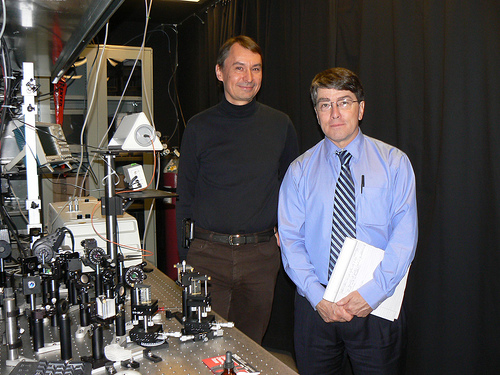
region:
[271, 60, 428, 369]
man standing wearing blue pants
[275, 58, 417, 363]
man standing holding white folder and blue long sleeve shirt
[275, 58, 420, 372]
man wearing blue striped tie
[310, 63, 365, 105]
dark hair on man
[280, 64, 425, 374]
man wearing glasses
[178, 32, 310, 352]
man standing wearing brown pants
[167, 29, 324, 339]
man wearing black shirt and black belt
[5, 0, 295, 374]
metal table with scientific equipment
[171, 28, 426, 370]
two scientists posing in picture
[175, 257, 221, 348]
microscope on metal table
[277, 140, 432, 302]
shirt on the person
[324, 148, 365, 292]
tie on the man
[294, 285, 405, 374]
pants on the person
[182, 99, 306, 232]
shirt on the person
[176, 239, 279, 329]
pants on the person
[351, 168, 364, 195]
pen in person's pocket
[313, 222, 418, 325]
paper in person's arm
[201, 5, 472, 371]
curtain behind the men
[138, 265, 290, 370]
table with equipment on it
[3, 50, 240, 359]
equipment for testing and experiments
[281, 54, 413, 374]
the man with his hands at his waist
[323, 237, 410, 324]
the white papers under his arm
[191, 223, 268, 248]
the black leather belt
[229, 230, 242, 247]
the buckle on the belt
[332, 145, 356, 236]
the stripped tie on the mans shirt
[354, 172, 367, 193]
the black cap of the pen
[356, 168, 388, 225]
the pen in the mans breast pocket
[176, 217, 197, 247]
the phone clipped on the belt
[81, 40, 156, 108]
the white cabinet agianst the wall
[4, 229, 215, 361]
the equipment on the workbench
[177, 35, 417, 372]
the two men standing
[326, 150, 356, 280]
the long striped tie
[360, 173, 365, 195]
the pen in the pocket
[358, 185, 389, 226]
the pocket on the man's shirt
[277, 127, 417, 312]
the long sleeved blue shirt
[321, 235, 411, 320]
the papers in the man's hands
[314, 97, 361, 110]
the glasses on the man's face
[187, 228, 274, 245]
the belt on the man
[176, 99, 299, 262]
the dark long sleeved shirt on the man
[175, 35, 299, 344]
the man wearing brown pants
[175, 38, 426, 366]
two guys standing next to each other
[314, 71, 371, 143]
the head of an old man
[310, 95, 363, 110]
the eyes of an old man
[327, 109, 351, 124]
the nose of an old man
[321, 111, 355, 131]
the mouth of an old man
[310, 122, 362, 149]
the neck of an old man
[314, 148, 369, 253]
the tie of an old man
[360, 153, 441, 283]
the arm of an old man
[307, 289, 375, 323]
the hands of an old man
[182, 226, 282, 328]
the pants of an old man